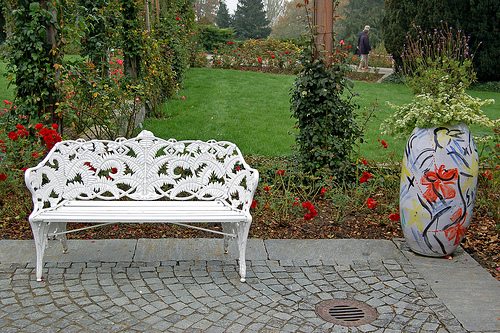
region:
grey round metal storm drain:
[315, 295, 379, 327]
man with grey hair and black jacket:
[357, 22, 377, 77]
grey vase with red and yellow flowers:
[397, 119, 478, 270]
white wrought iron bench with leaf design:
[23, 128, 258, 286]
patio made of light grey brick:
[0, 255, 448, 330]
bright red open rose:
[364, 193, 376, 211]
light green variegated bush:
[376, 87, 493, 138]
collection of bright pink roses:
[107, 54, 124, 92]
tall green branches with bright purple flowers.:
[402, 20, 484, 94]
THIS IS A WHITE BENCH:
[22, 133, 260, 283]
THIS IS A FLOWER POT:
[396, 125, 480, 259]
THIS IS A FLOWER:
[376, 20, 497, 137]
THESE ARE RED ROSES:
[252, 138, 404, 235]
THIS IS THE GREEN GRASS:
[136, 66, 498, 163]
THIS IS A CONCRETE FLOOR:
[0, 235, 495, 329]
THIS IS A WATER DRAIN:
[310, 295, 380, 329]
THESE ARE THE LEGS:
[35, 223, 259, 279]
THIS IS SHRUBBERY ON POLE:
[290, 48, 380, 188]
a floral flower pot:
[397, 113, 479, 257]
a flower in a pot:
[376, 83, 496, 260]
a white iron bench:
[25, 128, 260, 283]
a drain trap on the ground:
[312, 299, 375, 324]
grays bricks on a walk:
[80, 271, 200, 329]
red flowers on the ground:
[258, 166, 385, 232]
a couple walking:
[354, 21, 377, 73]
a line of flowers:
[193, 39, 300, 71]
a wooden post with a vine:
[308, 0, 339, 72]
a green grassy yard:
[194, 74, 283, 126]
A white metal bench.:
[25, 129, 259, 283]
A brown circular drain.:
[316, 295, 382, 327]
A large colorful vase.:
[396, 118, 480, 257]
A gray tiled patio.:
[0, 240, 499, 331]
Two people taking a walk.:
[355, 23, 375, 70]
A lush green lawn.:
[129, 63, 301, 153]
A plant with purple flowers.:
[390, 23, 484, 96]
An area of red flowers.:
[250, 138, 401, 238]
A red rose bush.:
[0, 116, 64, 218]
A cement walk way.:
[345, 65, 392, 75]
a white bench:
[15, 103, 269, 303]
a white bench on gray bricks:
[15, 120, 289, 307]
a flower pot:
[395, 77, 477, 261]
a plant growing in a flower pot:
[386, 76, 493, 150]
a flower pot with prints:
[390, 112, 479, 262]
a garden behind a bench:
[23, 82, 281, 289]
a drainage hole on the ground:
[312, 290, 385, 327]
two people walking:
[339, 12, 381, 79]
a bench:
[28, 125, 259, 275]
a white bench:
[24, 130, 261, 283]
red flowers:
[298, 198, 318, 220]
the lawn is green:
[210, 79, 250, 119]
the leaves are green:
[293, 55, 352, 177]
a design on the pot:
[401, 136, 463, 246]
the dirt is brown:
[301, 221, 338, 236]